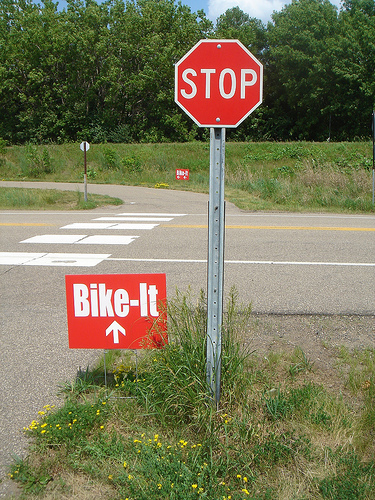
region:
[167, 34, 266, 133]
red and white street sign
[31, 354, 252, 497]
yellow flowers around street sign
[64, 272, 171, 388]
red and white Bike-It sign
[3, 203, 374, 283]
white lines painted on road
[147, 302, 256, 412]
grass around street sign pole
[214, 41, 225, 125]
silver bolts holding sign to post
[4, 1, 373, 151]
trees on other side of road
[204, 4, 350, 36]
clouds behind the trees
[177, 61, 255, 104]
white lettering on red sign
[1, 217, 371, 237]
double yellow line painted on road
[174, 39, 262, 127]
the red STOP sign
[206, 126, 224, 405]
the pole for the STOP sign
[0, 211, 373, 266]
the white lines on the ground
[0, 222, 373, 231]
the yellow lines on the ground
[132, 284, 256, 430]
the tall grass around the pole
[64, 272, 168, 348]
the red sign on the grass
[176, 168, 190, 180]
the red sign on the grass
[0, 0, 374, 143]
the trees behind the STOP sign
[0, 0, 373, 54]
the sky behind the trees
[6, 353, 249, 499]
the small yellow flowers on the ground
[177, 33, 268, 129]
Red stop sign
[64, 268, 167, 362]
Red bike-it sign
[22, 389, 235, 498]
Yellow flowers in the grass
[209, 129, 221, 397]
Silver pole holding stop sign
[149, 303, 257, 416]
Green bush by stop sign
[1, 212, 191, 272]
White street crossing sign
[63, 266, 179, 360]
White lettering on bike-it sign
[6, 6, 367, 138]
Large group of green trees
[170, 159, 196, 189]
Second red and white bike-it sign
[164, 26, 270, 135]
White lettering on stop sign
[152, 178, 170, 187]
Group of yellow flowers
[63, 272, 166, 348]
Red sign with white arrow pointing forward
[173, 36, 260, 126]
Stop sign at intersection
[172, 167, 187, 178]
Red sign on side of the road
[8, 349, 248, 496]
Group of yellow flowers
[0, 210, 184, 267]
Street intersection with crosswalk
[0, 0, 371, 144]
Leafy green trees behind stop sign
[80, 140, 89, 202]
Backside of a stop sign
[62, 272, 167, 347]
Red sign that read "Bike-It"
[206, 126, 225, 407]
Silver pole holding Stop sign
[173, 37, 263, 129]
octagonal stop sign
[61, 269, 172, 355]
sign that reads "bike it"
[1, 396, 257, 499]
dandelions among the grass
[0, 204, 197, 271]
white crosswalk lines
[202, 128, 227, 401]
steel sign post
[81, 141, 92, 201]
stop sign on a rusty pole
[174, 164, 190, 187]
sign with arrows pointing to the left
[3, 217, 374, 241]
yellow double lines in the road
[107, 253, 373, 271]
white line marking the shoulder of the road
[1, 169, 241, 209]
bike trail